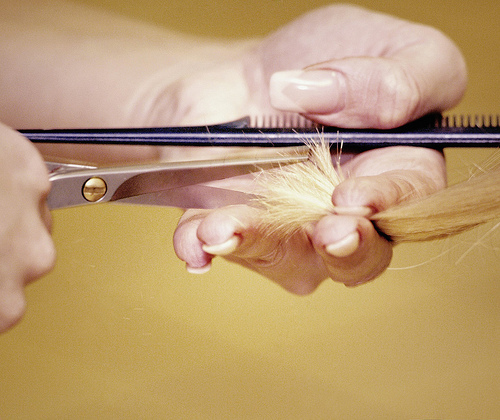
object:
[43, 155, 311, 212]
scissors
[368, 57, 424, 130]
knuckle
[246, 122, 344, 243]
ends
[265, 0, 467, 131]
finger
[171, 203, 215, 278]
finger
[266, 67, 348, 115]
fingernail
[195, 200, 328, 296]
finger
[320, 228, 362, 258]
nails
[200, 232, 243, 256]
nails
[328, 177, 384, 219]
fingertip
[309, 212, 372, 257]
fingertip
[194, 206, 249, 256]
fingertip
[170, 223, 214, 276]
fingertip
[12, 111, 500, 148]
black comb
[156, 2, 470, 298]
hairdresser hand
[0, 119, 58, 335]
hairdresser hand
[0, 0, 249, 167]
arm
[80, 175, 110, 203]
brass screw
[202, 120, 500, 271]
blond hair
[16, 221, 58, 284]
knuckles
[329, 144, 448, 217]
finger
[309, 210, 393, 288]
finger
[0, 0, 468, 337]
beautician